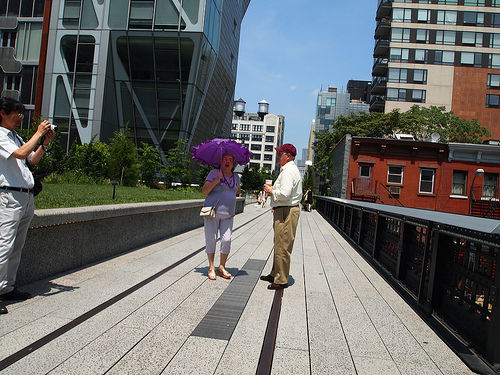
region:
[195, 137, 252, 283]
woman with a purple parasol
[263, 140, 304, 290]
man with a red hat holding a coffee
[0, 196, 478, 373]
long sidewalk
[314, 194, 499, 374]
black railing along sidewalk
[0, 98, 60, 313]
man on the left taking a picture with a camera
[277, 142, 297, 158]
red hat on the man's head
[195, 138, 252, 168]
purple parasol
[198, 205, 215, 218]
the woman's small beige purse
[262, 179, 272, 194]
coffee cup in the man's hand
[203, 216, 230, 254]
the woman's beige capri pants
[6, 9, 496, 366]
picture taken outside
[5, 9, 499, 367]
picture taken during the day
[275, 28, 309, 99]
the sky is void of clouds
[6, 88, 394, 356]
three people standing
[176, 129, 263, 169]
a purple umbrellas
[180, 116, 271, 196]
the woman holds an umbrellas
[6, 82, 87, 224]
a man holds a camera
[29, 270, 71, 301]
the shadow of the man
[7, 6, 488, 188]
the buildings in the background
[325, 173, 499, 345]
railing next to the people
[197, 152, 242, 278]
Woman with umbrella standing on walkway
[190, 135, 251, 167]
Purple umbrella held by a woman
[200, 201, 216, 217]
Beige purse of woman on walkway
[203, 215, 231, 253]
White pants of woman on walkway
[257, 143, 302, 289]
Man standing on a walkway next to a woman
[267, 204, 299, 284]
Beige pants on man next to a woman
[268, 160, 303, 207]
White shirt on man standing next to a woman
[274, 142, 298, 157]
Burgundy hat on man standing with a woman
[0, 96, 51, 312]
Man standing on a walkway taking a picture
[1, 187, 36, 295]
White pants on man standing taking a picture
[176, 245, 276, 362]
dark board on walkway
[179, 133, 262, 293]
woman holding an umbrella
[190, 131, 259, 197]
umbrella in woman's hand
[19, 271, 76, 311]
shadow of the man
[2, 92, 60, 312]
man taking a picture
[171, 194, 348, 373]
wood on the walkway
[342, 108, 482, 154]
tree tops along the building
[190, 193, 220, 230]
purse on the woman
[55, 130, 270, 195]
bushes along the walkway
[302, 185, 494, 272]
rail along the walkway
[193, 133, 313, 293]
an older couple standing in the middle of a walkway in the city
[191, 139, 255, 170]
purple umbrella with ruffled edges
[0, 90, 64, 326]
Asian man standing to the side taking a picture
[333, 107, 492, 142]
large green leafy trees near the buildings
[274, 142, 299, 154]
red cap the man is wearinf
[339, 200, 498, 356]
black railing along side the walkway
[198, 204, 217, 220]
white purse with a strap around the lady's shoulder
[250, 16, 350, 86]
very clear and blue sky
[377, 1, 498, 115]
tall building with many windows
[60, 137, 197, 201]
grass and low trees next to the walkway